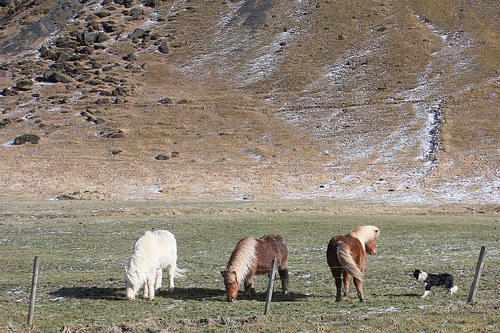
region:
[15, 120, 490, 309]
horses in a field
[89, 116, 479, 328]
small horses in a field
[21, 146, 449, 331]
a field with horses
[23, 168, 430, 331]
a field with small horses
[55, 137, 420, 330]
horses behind a fence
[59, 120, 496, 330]
horses in a fenced in area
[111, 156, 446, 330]
small horses in a fenced in area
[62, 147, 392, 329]
small horses behind fence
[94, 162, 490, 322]
horses and a dog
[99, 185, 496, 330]
horses and a dog behind the fence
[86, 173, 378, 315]
Three horses in the field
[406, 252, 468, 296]
dog herding the horses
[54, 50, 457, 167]
Mountain with a dusting of snow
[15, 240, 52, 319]
Fence pole in the ground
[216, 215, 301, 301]
Brown horse with a beige mane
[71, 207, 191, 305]
White horse with a white mane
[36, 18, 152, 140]
Rocks along the mountain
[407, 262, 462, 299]
Black and white dog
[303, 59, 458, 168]
snow on the mountain side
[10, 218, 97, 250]
Grass for grazing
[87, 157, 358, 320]
the horses are visible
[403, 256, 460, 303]
black and white dog located on right side of photo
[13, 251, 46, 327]
fence support pole on left of picture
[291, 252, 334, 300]
metal fence lines in front of horse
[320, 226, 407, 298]
miniature horse facing away from camera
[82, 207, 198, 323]
miniature white horse grazing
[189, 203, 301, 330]
miniature brown horse facing camera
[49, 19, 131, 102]
large rocks on mountainside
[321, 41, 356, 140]
white snow scattered on hillside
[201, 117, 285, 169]
brown dirt on hillside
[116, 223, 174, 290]
windblown mane of white horse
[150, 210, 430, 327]
the horses are visible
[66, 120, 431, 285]
the horses are visible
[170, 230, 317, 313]
the horses are visible